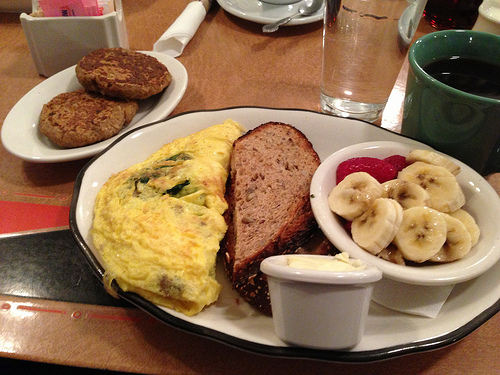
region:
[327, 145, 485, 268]
Bananas in the bowl.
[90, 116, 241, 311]
Omelet on the plate.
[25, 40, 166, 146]
Sausage on the plate.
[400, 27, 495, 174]
Green coffee cup on the table.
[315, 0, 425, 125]
Clear glass on the table.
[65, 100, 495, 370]
black rim on the plate.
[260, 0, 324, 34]
Metal spoon on the plate.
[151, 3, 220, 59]
White napkin on the table.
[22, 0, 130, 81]
Sugar packets in the container.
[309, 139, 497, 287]
Strawberries in the bowl.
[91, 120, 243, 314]
yellow egg omelette on the white plate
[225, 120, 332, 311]
brown toast on the white plate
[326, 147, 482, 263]
yellow banana in the white bowl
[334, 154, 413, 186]
red strawberries in the white bowl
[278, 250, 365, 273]
butter in the little white cup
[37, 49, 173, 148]
brown sausage patties on a small white plate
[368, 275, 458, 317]
white napkin on the white plate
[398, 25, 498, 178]
green coffee mug by the white plate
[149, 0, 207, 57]
white rolled up napkin on the table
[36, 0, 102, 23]
pink sugar packets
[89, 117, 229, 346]
omelette with a dark filling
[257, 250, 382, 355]
small sauce cup filled with butter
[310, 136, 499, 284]
white bowl filled with banana and strawberry slices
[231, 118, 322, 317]
slices of whole wheat bread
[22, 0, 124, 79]
partial view of a Sweet and Low and sugar holder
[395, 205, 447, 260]
single slice of banana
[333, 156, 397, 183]
single slice of strawberry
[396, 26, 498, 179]
dark green coffee cup with black coffee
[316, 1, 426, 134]
translucent water glass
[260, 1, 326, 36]
small metal spoon sitting on a white saucer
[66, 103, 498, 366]
white plate with black rim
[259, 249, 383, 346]
little white cup of butter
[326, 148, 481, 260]
yellow bananas in the white bowl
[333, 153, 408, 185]
red strawberries in a white bowl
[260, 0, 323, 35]
silver spoon on a white plate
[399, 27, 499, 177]
green mug next to the white plate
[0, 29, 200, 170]
plate with english muffin on it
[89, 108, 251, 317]
omelet on white plate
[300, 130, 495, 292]
white bowl with banana slices and strawberries in it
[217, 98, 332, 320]
stack of brown bread on plate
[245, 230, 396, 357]
small cup of butter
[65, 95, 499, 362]
white plate with black edges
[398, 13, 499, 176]
green cup full of black liquid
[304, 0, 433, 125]
empty glass on table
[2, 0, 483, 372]
brown table as background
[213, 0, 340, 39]
plate with spoon on it in background